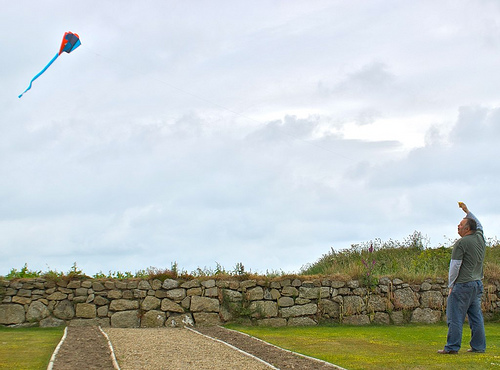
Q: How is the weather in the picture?
A: It is cloudy.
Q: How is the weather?
A: It is cloudy.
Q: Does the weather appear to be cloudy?
A: Yes, it is cloudy.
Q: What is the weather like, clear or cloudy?
A: It is cloudy.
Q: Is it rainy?
A: No, it is cloudy.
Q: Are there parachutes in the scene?
A: No, there are no parachutes.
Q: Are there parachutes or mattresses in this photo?
A: No, there are no parachutes or mattresses.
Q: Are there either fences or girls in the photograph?
A: No, there are no fences or girls.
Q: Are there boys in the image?
A: No, there are no boys.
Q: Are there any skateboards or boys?
A: No, there are no boys or skateboards.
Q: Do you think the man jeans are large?
A: Yes, the jeans are large.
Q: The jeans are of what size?
A: The jeans are large.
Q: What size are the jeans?
A: The jeans are large.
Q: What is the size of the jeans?
A: The jeans are large.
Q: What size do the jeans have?
A: The jeans have large size.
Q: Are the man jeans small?
A: No, the jeans are large.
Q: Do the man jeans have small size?
A: No, the jeans are large.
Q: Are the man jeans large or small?
A: The jeans are large.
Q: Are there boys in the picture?
A: No, there are no boys.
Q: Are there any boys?
A: No, there are no boys.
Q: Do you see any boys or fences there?
A: No, there are no boys or fences.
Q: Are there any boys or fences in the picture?
A: No, there are no boys or fences.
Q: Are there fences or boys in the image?
A: No, there are no boys or fences.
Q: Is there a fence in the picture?
A: No, there are no fences.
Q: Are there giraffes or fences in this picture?
A: No, there are no fences or giraffes.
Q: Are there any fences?
A: No, there are no fences.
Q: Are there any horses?
A: No, there are no horses.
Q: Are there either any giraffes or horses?
A: No, there are no horses or giraffes.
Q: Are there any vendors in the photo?
A: No, there are no vendors.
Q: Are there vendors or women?
A: No, there are no vendors or women.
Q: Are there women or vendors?
A: No, there are no vendors or women.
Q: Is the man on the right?
A: Yes, the man is on the right of the image.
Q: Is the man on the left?
A: No, the man is on the right of the image.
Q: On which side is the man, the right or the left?
A: The man is on the right of the image.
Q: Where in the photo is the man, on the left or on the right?
A: The man is on the right of the image.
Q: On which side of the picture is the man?
A: The man is on the right of the image.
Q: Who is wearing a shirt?
A: The man is wearing a shirt.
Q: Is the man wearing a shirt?
A: Yes, the man is wearing a shirt.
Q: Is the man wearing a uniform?
A: No, the man is wearing a shirt.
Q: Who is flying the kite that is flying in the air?
A: The man is flying the kite.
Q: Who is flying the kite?
A: The man is flying the kite.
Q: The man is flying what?
A: The man is flying the kite.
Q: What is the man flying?
A: The man is flying the kite.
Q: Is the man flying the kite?
A: Yes, the man is flying the kite.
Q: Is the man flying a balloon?
A: No, the man is flying the kite.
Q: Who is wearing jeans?
A: The man is wearing jeans.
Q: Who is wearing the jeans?
A: The man is wearing jeans.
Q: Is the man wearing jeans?
A: Yes, the man is wearing jeans.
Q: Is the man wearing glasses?
A: No, the man is wearing jeans.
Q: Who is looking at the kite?
A: The man is looking at the kite.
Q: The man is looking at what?
A: The man is looking at the kite.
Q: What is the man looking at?
A: The man is looking at the kite.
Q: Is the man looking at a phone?
A: No, the man is looking at the kite.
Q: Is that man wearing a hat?
A: No, the man is wearing a shirt.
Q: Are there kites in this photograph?
A: Yes, there is a kite.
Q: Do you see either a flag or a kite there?
A: Yes, there is a kite.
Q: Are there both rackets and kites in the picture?
A: No, there is a kite but no rackets.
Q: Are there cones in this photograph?
A: No, there are no cones.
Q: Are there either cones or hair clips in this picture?
A: No, there are no cones or hair clips.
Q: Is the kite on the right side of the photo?
A: No, the kite is on the left of the image.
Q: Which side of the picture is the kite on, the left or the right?
A: The kite is on the left of the image.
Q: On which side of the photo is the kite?
A: The kite is on the left of the image.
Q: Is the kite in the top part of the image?
A: Yes, the kite is in the top of the image.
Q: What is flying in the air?
A: The kite is flying in the air.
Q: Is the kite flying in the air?
A: Yes, the kite is flying in the air.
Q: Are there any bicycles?
A: No, there are no bicycles.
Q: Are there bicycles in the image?
A: No, there are no bicycles.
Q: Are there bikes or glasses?
A: No, there are no bikes or glasses.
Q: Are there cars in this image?
A: No, there are no cars.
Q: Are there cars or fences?
A: No, there are no cars or fences.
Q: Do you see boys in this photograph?
A: No, there are no boys.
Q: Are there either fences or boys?
A: No, there are no boys or fences.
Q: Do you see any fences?
A: No, there are no fences.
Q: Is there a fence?
A: No, there are no fences.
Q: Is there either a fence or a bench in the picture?
A: No, there are no fences or benches.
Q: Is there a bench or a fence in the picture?
A: No, there are no fences or benches.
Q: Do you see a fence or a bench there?
A: No, there are no fences or benches.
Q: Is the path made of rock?
A: Yes, the path is made of rock.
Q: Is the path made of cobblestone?
A: No, the path is made of rock.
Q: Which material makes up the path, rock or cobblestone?
A: The path is made of rock.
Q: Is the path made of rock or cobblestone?
A: The path is made of rock.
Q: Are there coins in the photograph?
A: No, there are no coins.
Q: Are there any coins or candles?
A: No, there are no coins or candles.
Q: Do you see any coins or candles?
A: No, there are no coins or candles.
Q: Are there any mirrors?
A: No, there are no mirrors.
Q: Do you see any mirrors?
A: No, there are no mirrors.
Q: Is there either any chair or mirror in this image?
A: No, there are no mirrors or chairs.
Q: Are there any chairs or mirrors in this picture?
A: No, there are no mirrors or chairs.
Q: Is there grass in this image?
A: Yes, there is grass.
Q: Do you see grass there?
A: Yes, there is grass.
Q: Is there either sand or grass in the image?
A: Yes, there is grass.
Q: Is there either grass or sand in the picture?
A: Yes, there is grass.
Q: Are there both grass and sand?
A: No, there is grass but no sand.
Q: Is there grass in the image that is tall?
A: Yes, there is tall grass.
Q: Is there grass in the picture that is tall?
A: Yes, there is grass that is tall.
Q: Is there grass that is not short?
A: Yes, there is tall grass.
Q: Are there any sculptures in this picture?
A: No, there are no sculptures.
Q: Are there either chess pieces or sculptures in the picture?
A: No, there are no sculptures or chess pieces.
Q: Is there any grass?
A: Yes, there is grass.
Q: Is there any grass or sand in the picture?
A: Yes, there is grass.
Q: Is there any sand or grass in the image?
A: Yes, there is grass.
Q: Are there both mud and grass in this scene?
A: No, there is grass but no mud.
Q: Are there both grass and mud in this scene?
A: No, there is grass but no mud.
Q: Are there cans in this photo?
A: No, there are no cans.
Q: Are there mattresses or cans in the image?
A: No, there are no cans or mattresses.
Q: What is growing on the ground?
A: The grass is growing on the ground.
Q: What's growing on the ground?
A: The grass is growing on the ground.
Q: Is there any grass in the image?
A: Yes, there is grass.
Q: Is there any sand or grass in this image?
A: Yes, there is grass.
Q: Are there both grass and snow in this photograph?
A: No, there is grass but no snow.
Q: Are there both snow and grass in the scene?
A: No, there is grass but no snow.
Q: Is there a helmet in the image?
A: No, there are no helmets.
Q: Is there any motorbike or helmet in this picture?
A: No, there are no helmets or motorcycles.